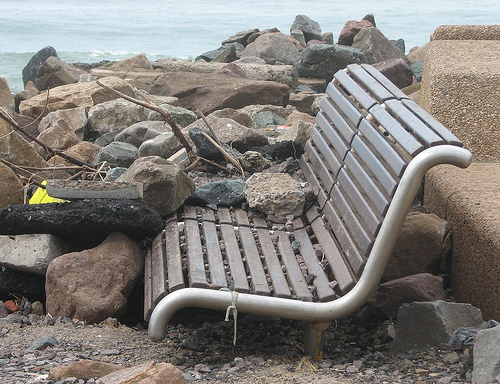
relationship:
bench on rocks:
[142, 57, 474, 352] [15, 10, 435, 216]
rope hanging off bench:
[225, 290, 238, 346] [149, 174, 444, 298]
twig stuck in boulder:
[9, 159, 86, 199] [294, 40, 362, 77]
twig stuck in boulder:
[5, 107, 85, 164] [241, 36, 300, 67]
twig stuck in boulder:
[93, 77, 190, 152] [159, 72, 287, 108]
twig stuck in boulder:
[193, 108, 216, 137] [23, 47, 63, 84]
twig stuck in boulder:
[201, 128, 240, 173] [40, 235, 155, 317]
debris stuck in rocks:
[23, 167, 83, 214] [10, 110, 191, 195]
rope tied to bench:
[224, 290, 239, 343] [142, 57, 474, 352]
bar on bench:
[177, 216, 213, 289] [135, 28, 493, 368]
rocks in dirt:
[78, 70, 268, 208] [66, 320, 191, 366]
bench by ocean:
[144, 63, 474, 363] [14, 3, 236, 29]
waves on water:
[70, 40, 137, 71] [65, 6, 277, 61]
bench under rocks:
[144, 63, 474, 363] [15, 10, 435, 216]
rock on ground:
[240, 170, 305, 222] [1, 301, 461, 381]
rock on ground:
[45, 229, 145, 324] [1, 301, 461, 381]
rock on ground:
[30, 118, 82, 152] [1, 301, 461, 381]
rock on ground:
[187, 124, 232, 166] [1, 301, 461, 381]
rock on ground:
[238, 28, 305, 65] [1, 301, 461, 381]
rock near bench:
[240, 170, 305, 222] [144, 63, 474, 363]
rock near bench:
[45, 229, 145, 324] [144, 63, 474, 363]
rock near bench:
[30, 118, 82, 152] [144, 63, 474, 363]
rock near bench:
[187, 124, 232, 166] [144, 63, 474, 363]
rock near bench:
[238, 28, 305, 65] [144, 63, 474, 363]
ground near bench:
[1, 301, 461, 381] [144, 63, 474, 363]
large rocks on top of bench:
[36, 42, 302, 208] [144, 63, 474, 363]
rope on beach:
[225, 290, 238, 346] [13, 52, 492, 377]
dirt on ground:
[124, 347, 176, 359] [0, 34, 497, 379]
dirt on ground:
[5, 323, 125, 340] [0, 34, 497, 379]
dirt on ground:
[247, 367, 347, 382] [0, 34, 497, 379]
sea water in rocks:
[0, 2, 495, 64] [4, 14, 484, 366]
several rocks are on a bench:
[19, 69, 322, 216] [144, 63, 474, 363]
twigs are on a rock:
[12, 154, 115, 200] [190, 117, 265, 154]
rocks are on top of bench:
[16, 24, 306, 221] [142, 57, 474, 352]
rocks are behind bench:
[378, 266, 495, 363] [144, 63, 474, 363]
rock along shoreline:
[241, 162, 313, 222] [2, 2, 492, 123]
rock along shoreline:
[194, 178, 255, 204] [2, 2, 492, 123]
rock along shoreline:
[277, 114, 319, 146] [2, 2, 492, 123]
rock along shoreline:
[205, 108, 273, 151] [2, 2, 492, 123]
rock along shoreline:
[139, 72, 290, 114] [2, 2, 492, 123]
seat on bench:
[140, 182, 348, 336] [142, 57, 474, 352]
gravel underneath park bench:
[8, 301, 474, 376] [133, 54, 478, 356]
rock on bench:
[240, 170, 305, 222] [142, 57, 474, 352]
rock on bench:
[194, 177, 249, 204] [142, 57, 474, 352]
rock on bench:
[117, 159, 193, 214] [142, 57, 474, 352]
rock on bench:
[238, 147, 270, 168] [142, 57, 474, 352]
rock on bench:
[187, 125, 243, 165] [142, 57, 474, 352]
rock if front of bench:
[45, 229, 145, 324] [142, 57, 474, 352]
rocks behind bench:
[327, 322, 475, 382] [154, 81, 484, 323]